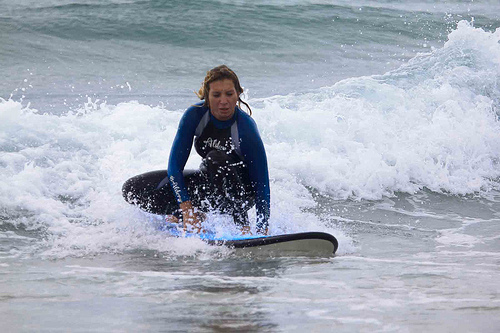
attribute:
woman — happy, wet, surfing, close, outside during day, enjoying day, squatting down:
[121, 63, 271, 237]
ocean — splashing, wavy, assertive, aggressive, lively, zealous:
[1, 1, 499, 333]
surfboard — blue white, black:
[159, 224, 337, 258]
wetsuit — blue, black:
[121, 101, 270, 225]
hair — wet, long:
[193, 63, 253, 114]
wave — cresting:
[1, 17, 499, 222]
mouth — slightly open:
[218, 107, 231, 112]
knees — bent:
[122, 148, 227, 198]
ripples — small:
[0, 2, 499, 72]